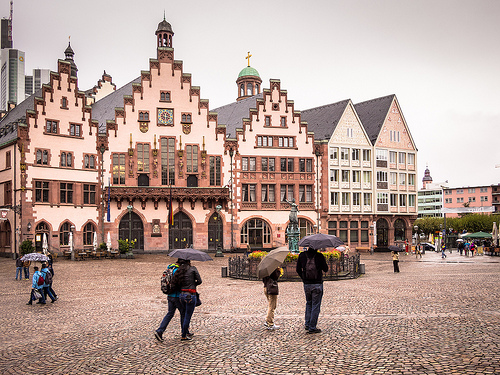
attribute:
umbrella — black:
[298, 232, 337, 253]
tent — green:
[454, 229, 496, 237]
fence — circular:
[216, 247, 365, 290]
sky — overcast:
[402, 37, 447, 57]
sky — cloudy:
[373, 31, 497, 119]